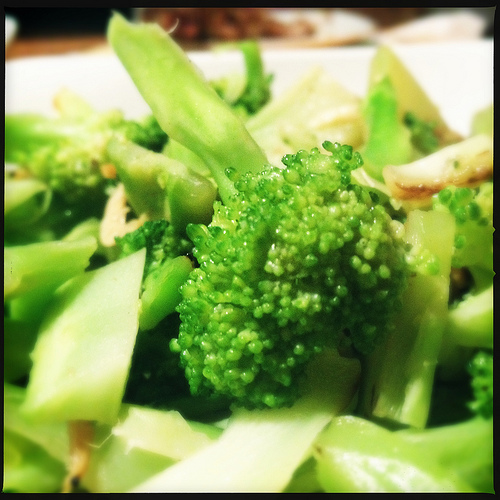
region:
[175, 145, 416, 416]
the food is green in color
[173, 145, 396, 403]
the food is broccoli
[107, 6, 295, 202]
a broccoli stem is sticking out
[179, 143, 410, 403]
the broccoli is moist and wet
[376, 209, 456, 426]
the broccoli is light green in color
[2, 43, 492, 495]
the plate is white in color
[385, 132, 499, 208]
the vegetable stem is fried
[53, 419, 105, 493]
a small stem is light brown in color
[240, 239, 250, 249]
the grain of broccoli is reflecting light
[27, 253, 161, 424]
the vegetable stem is laying flat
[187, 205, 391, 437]
Green broccoli.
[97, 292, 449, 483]
Vegetables that are green.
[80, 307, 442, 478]
Contains lots of fiber.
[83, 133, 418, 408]
Broccoli heads are good fro eating.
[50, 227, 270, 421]
Fresh vegetables.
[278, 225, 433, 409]
Broccoli for dipping in ranch.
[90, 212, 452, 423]
Broccoli can be used for many dishes.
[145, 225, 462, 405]
Broccoli is very good for you.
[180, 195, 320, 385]
Broccoli can be made into soup.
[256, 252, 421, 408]
Freshly rinsed broccoli.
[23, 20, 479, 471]
fresh stir-fired broccoli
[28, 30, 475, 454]
lightly cooked broccoli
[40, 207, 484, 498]
broccoli stems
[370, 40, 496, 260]
onion on top of piece of broccoli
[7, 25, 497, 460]
Close-up of vegetables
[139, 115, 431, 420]
light green broccoli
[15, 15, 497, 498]
broccoli is on a white plate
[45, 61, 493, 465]
chopped broccoli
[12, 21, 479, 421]
vegetarian meal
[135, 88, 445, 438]
broccoli floret in the middle of dish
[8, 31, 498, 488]
Dish of meal on table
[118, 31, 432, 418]
Broccoli florets on top of food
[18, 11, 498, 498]
Food served on a dish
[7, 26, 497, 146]
Dish is white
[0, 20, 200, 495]
Steam of broccoli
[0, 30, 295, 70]
Dish is over a table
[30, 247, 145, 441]
Broccoli steam cutting in a triangle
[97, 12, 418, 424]
Steam of broccoli is facing up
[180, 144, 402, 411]
Buds of broccoli are facing down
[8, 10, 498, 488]
Many broccoli steams on dish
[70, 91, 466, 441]
different pieces of broccoli mixed together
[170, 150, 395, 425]
broccoli floret composed of tiny round heads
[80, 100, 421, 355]
broccoli spanning the hues from yellowish green to dark green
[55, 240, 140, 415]
smooth surface of cut stem of broccoli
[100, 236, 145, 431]
sharp edge of a spear of broccoli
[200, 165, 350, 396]
bumpy texture of a floret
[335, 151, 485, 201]
brown char from stir fry cooking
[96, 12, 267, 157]
slanted cut of broccoli stem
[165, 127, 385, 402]
shiny surfaces from being cooked in oil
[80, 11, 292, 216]
broccoli stem sticking straight out of dish